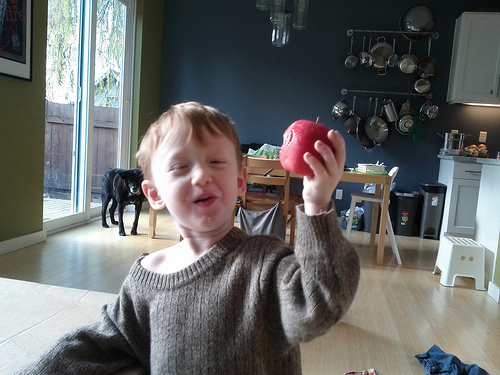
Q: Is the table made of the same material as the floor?
A: Yes, both the table and the floor are made of wood.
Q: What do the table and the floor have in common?
A: The material, both the table and the floor are wooden.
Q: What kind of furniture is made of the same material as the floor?
A: The table is made of the same material as the floor.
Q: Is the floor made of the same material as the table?
A: Yes, both the floor and the table are made of wood.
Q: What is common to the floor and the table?
A: The material, both the floor and the table are wooden.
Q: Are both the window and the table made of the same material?
A: No, the window is made of glass and the table is made of wood.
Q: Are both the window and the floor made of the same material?
A: No, the window is made of glass and the floor is made of wood.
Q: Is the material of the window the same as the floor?
A: No, the window is made of glass and the floor is made of wood.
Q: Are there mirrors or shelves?
A: No, there are no shelves or mirrors.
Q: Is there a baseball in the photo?
A: No, there are no baseballs.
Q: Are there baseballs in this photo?
A: No, there are no baseballs.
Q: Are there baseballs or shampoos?
A: No, there are no baseballs or shampoos.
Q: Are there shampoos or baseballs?
A: No, there are no baseballs or shampoos.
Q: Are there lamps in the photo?
A: Yes, there is a lamp.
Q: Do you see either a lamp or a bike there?
A: Yes, there is a lamp.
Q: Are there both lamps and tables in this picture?
A: Yes, there are both a lamp and a table.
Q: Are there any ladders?
A: No, there are no ladders.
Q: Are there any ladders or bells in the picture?
A: No, there are no ladders or bells.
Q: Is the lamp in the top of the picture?
A: Yes, the lamp is in the top of the image.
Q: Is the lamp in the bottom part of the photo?
A: No, the lamp is in the top of the image.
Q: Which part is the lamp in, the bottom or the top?
A: The lamp is in the top of the image.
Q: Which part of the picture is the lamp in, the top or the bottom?
A: The lamp is in the top of the image.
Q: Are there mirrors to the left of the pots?
A: No, there is a lamp to the left of the pots.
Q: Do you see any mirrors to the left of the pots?
A: No, there is a lamp to the left of the pots.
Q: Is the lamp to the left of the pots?
A: Yes, the lamp is to the left of the pots.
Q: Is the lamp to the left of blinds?
A: No, the lamp is to the left of the pots.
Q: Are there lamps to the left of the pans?
A: Yes, there is a lamp to the left of the pans.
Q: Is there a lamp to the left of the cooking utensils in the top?
A: Yes, there is a lamp to the left of the pans.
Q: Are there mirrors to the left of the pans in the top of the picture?
A: No, there is a lamp to the left of the pans.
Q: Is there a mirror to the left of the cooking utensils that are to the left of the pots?
A: No, there is a lamp to the left of the pans.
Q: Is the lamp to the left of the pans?
A: Yes, the lamp is to the left of the pans.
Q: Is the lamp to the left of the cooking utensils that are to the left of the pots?
A: Yes, the lamp is to the left of the pans.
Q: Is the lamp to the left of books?
A: No, the lamp is to the left of the pans.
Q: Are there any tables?
A: Yes, there is a table.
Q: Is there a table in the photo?
A: Yes, there is a table.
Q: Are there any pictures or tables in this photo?
A: Yes, there is a table.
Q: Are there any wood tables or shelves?
A: Yes, there is a wood table.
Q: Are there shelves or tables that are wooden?
A: Yes, the table is wooden.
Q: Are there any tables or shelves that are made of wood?
A: Yes, the table is made of wood.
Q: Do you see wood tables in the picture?
A: Yes, there is a wood table.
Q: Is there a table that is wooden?
A: Yes, there is a table that is wooden.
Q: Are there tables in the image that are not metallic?
A: Yes, there is a wooden table.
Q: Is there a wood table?
A: Yes, there is a table that is made of wood.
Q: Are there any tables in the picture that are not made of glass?
A: Yes, there is a table that is made of wood.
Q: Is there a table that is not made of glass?
A: Yes, there is a table that is made of wood.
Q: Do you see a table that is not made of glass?
A: Yes, there is a table that is made of wood.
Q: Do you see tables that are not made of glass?
A: Yes, there is a table that is made of wood.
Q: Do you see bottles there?
A: No, there are no bottles.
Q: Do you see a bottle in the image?
A: No, there are no bottles.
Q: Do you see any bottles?
A: No, there are no bottles.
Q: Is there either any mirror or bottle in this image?
A: No, there are no bottles or mirrors.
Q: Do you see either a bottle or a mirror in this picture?
A: No, there are no bottles or mirrors.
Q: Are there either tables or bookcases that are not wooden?
A: No, there is a table but it is wooden.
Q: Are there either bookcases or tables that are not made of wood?
A: No, there is a table but it is made of wood.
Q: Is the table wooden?
A: Yes, the table is wooden.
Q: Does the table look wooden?
A: Yes, the table is wooden.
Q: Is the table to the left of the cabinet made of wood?
A: Yes, the table is made of wood.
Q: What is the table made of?
A: The table is made of wood.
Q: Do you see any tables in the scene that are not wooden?
A: No, there is a table but it is wooden.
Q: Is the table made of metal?
A: No, the table is made of wood.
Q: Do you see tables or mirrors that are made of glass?
A: No, there is a table but it is made of wood.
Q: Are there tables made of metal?
A: No, there is a table but it is made of wood.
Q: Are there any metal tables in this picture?
A: No, there is a table but it is made of wood.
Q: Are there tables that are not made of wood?
A: No, there is a table but it is made of wood.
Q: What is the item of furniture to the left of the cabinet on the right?
A: The piece of furniture is a table.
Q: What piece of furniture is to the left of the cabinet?
A: The piece of furniture is a table.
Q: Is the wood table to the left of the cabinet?
A: Yes, the table is to the left of the cabinet.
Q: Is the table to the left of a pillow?
A: No, the table is to the left of the cabinet.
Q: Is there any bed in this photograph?
A: No, there are no beds.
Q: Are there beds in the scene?
A: No, there are no beds.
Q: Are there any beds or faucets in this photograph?
A: No, there are no beds or faucets.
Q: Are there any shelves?
A: No, there are no shelves.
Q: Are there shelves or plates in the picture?
A: No, there are no shelves or plates.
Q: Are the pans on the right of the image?
A: Yes, the pans are on the right of the image.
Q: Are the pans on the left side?
A: No, the pans are on the right of the image.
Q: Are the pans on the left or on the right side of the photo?
A: The pans are on the right of the image.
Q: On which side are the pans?
A: The pans are on the right of the image.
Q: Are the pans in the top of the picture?
A: Yes, the pans are in the top of the image.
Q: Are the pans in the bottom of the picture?
A: No, the pans are in the top of the image.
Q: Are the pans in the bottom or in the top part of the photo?
A: The pans are in the top of the image.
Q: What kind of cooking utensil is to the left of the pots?
A: The cooking utensils are pans.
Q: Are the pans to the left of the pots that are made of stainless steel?
A: Yes, the pans are to the left of the pots.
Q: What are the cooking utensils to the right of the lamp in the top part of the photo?
A: The cooking utensils are pans.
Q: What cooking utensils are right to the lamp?
A: The cooking utensils are pans.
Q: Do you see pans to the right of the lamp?
A: Yes, there are pans to the right of the lamp.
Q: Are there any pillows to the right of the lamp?
A: No, there are pans to the right of the lamp.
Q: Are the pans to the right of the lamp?
A: Yes, the pans are to the right of the lamp.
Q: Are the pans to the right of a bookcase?
A: No, the pans are to the right of the lamp.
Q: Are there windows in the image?
A: Yes, there is a window.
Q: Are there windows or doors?
A: Yes, there is a window.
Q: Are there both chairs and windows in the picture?
A: Yes, there are both a window and a chair.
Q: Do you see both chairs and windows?
A: Yes, there are both a window and a chair.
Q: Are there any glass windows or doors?
A: Yes, there is a glass window.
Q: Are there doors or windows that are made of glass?
A: Yes, the window is made of glass.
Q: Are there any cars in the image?
A: No, there are no cars.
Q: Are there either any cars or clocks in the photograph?
A: No, there are no cars or clocks.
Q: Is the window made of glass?
A: Yes, the window is made of glass.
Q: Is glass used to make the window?
A: Yes, the window is made of glass.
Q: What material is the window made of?
A: The window is made of glass.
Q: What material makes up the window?
A: The window is made of glass.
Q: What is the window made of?
A: The window is made of glass.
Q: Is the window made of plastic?
A: No, the window is made of glass.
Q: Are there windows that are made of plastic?
A: No, there is a window but it is made of glass.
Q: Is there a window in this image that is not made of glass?
A: No, there is a window but it is made of glass.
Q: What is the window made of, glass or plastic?
A: The window is made of glass.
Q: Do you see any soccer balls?
A: No, there are no soccer balls.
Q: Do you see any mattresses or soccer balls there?
A: No, there are no soccer balls or mattresses.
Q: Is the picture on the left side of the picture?
A: Yes, the picture is on the left of the image.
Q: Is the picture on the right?
A: No, the picture is on the left of the image.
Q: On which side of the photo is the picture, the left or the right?
A: The picture is on the left of the image.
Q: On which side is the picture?
A: The picture is on the left of the image.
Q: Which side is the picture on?
A: The picture is on the left of the image.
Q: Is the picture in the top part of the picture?
A: Yes, the picture is in the top of the image.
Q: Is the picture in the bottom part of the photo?
A: No, the picture is in the top of the image.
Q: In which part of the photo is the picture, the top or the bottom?
A: The picture is in the top of the image.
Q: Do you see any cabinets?
A: Yes, there is a cabinet.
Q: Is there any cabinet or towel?
A: Yes, there is a cabinet.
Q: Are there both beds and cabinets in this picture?
A: No, there is a cabinet but no beds.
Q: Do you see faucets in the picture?
A: No, there are no faucets.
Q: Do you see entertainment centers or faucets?
A: No, there are no faucets or entertainment centers.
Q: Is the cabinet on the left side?
A: No, the cabinet is on the right of the image.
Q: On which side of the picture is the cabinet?
A: The cabinet is on the right of the image.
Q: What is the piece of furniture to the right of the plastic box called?
A: The piece of furniture is a cabinet.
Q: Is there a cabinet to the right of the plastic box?
A: Yes, there is a cabinet to the right of the box.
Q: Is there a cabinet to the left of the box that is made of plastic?
A: No, the cabinet is to the right of the box.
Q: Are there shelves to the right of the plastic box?
A: No, there is a cabinet to the right of the box.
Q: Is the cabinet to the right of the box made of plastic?
A: Yes, the cabinet is to the right of the box.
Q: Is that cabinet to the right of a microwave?
A: No, the cabinet is to the right of the box.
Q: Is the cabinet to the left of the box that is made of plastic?
A: No, the cabinet is to the right of the box.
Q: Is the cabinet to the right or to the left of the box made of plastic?
A: The cabinet is to the right of the box.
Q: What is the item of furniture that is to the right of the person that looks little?
A: The piece of furniture is a cabinet.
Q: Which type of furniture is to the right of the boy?
A: The piece of furniture is a cabinet.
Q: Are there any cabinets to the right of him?
A: Yes, there is a cabinet to the right of the boy.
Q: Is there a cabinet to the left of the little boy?
A: No, the cabinet is to the right of the boy.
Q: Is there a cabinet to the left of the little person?
A: No, the cabinet is to the right of the boy.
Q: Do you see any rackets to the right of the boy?
A: No, there is a cabinet to the right of the boy.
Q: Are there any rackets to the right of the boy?
A: No, there is a cabinet to the right of the boy.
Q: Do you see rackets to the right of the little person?
A: No, there is a cabinet to the right of the boy.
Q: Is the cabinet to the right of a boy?
A: Yes, the cabinet is to the right of a boy.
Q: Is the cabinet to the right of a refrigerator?
A: No, the cabinet is to the right of a boy.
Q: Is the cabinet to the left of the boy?
A: No, the cabinet is to the right of the boy.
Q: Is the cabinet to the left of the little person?
A: No, the cabinet is to the right of the boy.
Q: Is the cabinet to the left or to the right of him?
A: The cabinet is to the right of the boy.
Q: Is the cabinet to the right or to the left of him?
A: The cabinet is to the right of the boy.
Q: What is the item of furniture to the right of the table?
A: The piece of furniture is a cabinet.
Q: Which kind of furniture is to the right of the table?
A: The piece of furniture is a cabinet.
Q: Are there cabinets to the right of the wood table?
A: Yes, there is a cabinet to the right of the table.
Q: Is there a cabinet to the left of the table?
A: No, the cabinet is to the right of the table.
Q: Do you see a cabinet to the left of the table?
A: No, the cabinet is to the right of the table.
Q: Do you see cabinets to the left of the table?
A: No, the cabinet is to the right of the table.